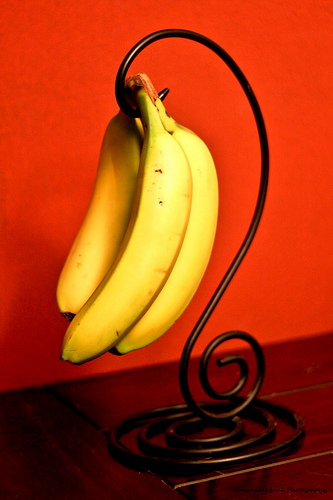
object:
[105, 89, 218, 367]
bananas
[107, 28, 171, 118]
hook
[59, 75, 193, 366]
banana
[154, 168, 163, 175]
brown spots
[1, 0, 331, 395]
wall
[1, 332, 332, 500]
table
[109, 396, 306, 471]
base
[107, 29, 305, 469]
banana stand